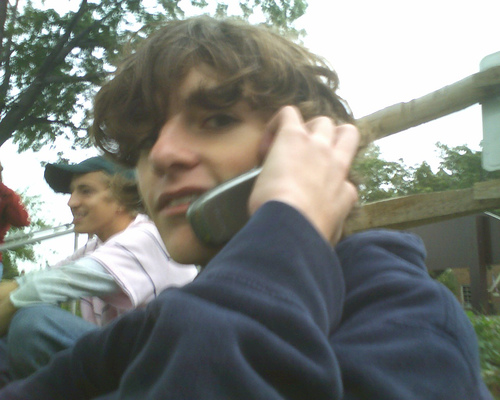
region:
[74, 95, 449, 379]
the guy is on the phone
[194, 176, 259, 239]
the phone is silver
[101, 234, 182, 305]
the shirt is pink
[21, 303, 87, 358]
the jeans are blue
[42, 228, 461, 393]
the jumper is blue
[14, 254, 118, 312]
the sleeves are white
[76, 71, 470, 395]
the guy is lokking at the camera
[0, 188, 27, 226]
the clothing is red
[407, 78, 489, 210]
the fence is wooden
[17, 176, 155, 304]
the guy is smiling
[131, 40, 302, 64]
brown curvy hair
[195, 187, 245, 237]
black mobile phone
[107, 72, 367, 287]
a boy using a mobile phone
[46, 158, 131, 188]
a black cap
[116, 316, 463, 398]
a black jumper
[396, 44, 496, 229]
wooden fence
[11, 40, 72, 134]
a tree with dark green leaves and a dark trunk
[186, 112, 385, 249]
a boy holding a mobile phone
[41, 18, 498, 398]
boys seated near a fence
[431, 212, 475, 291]
house on the backgground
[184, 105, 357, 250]
Hand holding a cell phone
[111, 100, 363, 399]
Arm with blue sleeve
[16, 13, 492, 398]
Boy holding a cell phone to his ear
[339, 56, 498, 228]
Brown, wood fence slats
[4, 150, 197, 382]
Boy wearing a baseball cap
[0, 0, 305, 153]
Tree branches providing shade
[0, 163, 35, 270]
Person's arm with red sleeve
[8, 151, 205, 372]
Boy wearing a pink shirt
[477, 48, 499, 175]
The edge of a sign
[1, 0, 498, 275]
Sky is gray and overcast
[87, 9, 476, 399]
boy talking by cell phone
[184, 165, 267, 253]
cell phone is black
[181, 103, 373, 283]
hand holding a cell phone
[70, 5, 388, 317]
boy talks on a cell phone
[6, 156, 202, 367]
boy wears a green cap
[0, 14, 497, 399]
wood fence behind boys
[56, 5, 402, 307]
boy has bangs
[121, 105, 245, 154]
brown eyes of boy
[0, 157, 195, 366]
boy wears white shirt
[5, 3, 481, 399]
a tree on side a fence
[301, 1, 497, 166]
glowing light in daytime sky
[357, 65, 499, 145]
wood post of fence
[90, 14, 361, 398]
boy with phone in hand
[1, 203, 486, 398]
blue sweatshirt with hood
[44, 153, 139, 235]
boy in baseball cap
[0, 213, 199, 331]
two shirts on body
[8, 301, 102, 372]
blue jeans on knee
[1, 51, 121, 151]
green leaves on tree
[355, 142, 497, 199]
leaves on tree tops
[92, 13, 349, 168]
curley brown hair on head